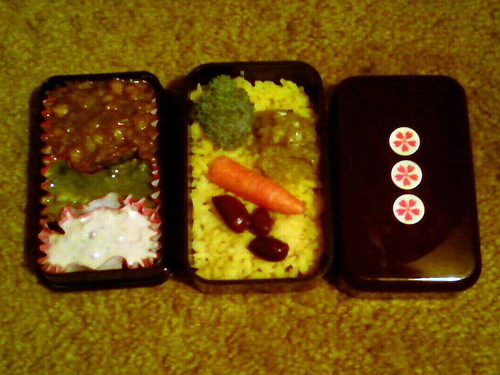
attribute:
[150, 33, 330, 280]
dish — black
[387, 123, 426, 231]
circles — white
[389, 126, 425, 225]
logo — white, red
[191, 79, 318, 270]
rice — yellow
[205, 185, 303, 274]
olives — dark green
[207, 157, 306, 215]
carrot — short, thick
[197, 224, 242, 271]
yellow rice — Yellow 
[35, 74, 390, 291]
black bowl — black 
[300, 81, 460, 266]
box — black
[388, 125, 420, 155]
circle — white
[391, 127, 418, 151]
flower — red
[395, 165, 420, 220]
flowers — red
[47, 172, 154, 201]
sauce — green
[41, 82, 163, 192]
beans — dark green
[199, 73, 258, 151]
curry — green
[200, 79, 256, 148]
item — green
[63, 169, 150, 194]
sauce — green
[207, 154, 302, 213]
carrot — orange